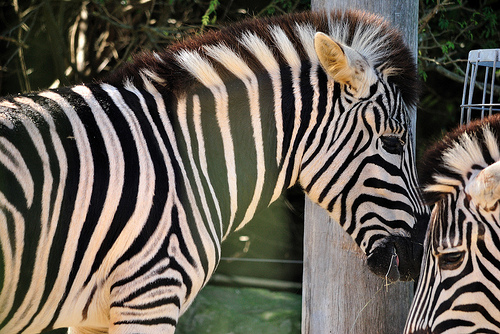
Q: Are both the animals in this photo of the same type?
A: Yes, all the animals are zebras.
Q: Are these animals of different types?
A: No, all the animals are zebras.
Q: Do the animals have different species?
A: No, all the animals are zebras.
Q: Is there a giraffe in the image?
A: No, there are no giraffes.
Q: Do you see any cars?
A: No, there are no cars.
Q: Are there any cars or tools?
A: No, there are no cars or tools.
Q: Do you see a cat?
A: No, there are no cats.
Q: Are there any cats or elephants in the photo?
A: No, there are no cats or elephants.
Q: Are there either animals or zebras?
A: Yes, there is a zebra.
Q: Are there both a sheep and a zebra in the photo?
A: No, there is a zebra but no sheep.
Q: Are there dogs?
A: No, there are no dogs.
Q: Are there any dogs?
A: No, there are no dogs.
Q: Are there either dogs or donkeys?
A: No, there are no dogs or donkeys.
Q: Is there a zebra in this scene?
A: Yes, there is a zebra.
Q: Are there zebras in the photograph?
A: Yes, there is a zebra.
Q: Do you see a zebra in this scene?
A: Yes, there is a zebra.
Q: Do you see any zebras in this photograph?
A: Yes, there is a zebra.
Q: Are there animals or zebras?
A: Yes, there is a zebra.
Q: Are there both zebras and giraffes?
A: No, there is a zebra but no giraffes.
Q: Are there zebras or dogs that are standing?
A: Yes, the zebra is standing.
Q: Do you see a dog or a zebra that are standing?
A: Yes, the zebra is standing.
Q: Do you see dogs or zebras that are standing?
A: Yes, the zebra is standing.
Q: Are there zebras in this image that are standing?
A: Yes, there is a zebra that is standing.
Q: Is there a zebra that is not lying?
A: Yes, there is a zebra that is standing.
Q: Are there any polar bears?
A: No, there are no polar bears.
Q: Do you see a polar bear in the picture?
A: No, there are no polar bears.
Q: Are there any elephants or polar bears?
A: No, there are no polar bears or elephants.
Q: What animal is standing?
A: The animal is a zebra.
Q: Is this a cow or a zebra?
A: This is a zebra.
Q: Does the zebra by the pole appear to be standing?
A: Yes, the zebra is standing.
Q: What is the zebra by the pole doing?
A: The zebra is standing.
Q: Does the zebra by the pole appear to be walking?
A: No, the zebra is standing.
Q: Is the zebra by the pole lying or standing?
A: The zebra is standing.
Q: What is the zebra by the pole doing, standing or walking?
A: The zebra is standing.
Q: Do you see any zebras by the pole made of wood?
A: Yes, there is a zebra by the pole.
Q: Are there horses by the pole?
A: No, there is a zebra by the pole.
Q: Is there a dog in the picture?
A: No, there are no dogs.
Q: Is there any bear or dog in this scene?
A: No, there are no dogs or bears.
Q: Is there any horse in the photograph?
A: No, there are no horses.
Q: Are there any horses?
A: No, there are no horses.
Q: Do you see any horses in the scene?
A: No, there are no horses.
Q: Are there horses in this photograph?
A: No, there are no horses.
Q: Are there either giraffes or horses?
A: No, there are no horses or giraffes.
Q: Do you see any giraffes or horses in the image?
A: No, there are no horses or giraffes.